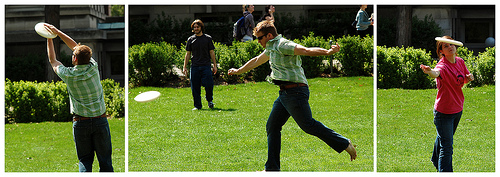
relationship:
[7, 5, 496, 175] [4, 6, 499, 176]
collage of pictures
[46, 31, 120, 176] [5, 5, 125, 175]
man in left picture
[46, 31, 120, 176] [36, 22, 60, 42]
man catching frisbee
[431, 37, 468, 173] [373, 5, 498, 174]
woman in pictures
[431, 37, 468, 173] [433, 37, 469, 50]
woman with a frisbee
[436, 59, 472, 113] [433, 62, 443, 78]
shirt has short sleeves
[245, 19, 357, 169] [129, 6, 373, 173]
man in middle picture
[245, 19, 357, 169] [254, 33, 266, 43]
man wearing sunglasses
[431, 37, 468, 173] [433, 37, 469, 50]
woman tossing a frisbee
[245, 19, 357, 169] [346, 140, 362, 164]
man has foot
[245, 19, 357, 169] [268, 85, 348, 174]
man wearing jeans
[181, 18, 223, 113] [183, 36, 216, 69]
man wearing shirt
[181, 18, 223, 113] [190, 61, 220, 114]
man wearing jeans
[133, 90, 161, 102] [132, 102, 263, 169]
frisbee near grass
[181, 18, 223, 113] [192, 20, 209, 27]
man has hair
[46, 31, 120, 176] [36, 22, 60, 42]
man catching a frisbee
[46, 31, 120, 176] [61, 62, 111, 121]
man wearing shirt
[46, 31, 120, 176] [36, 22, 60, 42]
man holding frisbee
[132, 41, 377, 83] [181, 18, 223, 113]
bushes are behind man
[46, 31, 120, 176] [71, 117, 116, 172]
man wearing jeans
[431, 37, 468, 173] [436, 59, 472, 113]
woman wearing a shirt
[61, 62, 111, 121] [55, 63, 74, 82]
shirt has short sleeves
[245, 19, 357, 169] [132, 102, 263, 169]
man jumping in grass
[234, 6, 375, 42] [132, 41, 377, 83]
people are behind bushes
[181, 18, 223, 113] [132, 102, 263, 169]
man in grass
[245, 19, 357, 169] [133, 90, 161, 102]
man throwing a frisbee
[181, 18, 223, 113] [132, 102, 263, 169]
man standing on grass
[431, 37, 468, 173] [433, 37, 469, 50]
woman throwing a frisbee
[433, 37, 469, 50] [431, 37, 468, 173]
frisbee in front of a woman